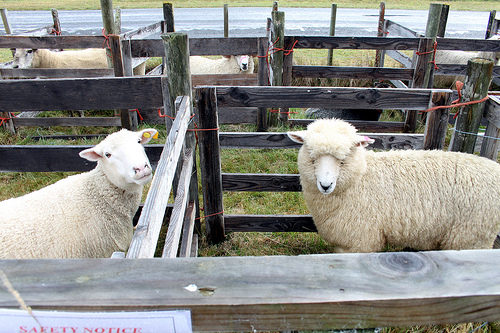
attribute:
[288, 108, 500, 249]
sheep — looking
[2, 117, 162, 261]
sheep — looking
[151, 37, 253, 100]
sheep — looking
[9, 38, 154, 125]
sheep — sheared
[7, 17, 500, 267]
sheep — white, waiting, fluffy, big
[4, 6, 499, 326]
fence — wooden, large, brown, gray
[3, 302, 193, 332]
sign — white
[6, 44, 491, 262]
grass — green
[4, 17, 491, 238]
string — red, orange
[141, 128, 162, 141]
tag — yellow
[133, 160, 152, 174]
nose — pink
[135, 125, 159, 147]
ear — tagged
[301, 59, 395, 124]
sheep — black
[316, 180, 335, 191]
nose — black